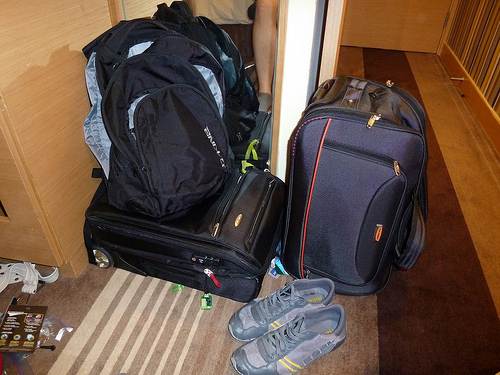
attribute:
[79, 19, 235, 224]
back pack — black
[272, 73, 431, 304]
suitcase — blue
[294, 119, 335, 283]
stripe — red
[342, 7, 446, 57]
door — wooden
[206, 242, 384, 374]
shoes — black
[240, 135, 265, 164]
tag — yellow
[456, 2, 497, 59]
wall — multicolored , striped 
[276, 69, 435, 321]
backpack — black, white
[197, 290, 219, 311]
tag — green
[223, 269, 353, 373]
tennis shoes — grey, yellow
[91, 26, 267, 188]
backpack — black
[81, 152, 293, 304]
bag — small, black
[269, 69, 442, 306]
bag — big, blue, red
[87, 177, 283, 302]
suitcase — black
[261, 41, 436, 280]
luggage — black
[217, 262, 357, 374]
shoe — grey, athletic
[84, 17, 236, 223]
backpack — black, blue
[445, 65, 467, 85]
door stop — metal 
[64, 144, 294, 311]
luggage — black 